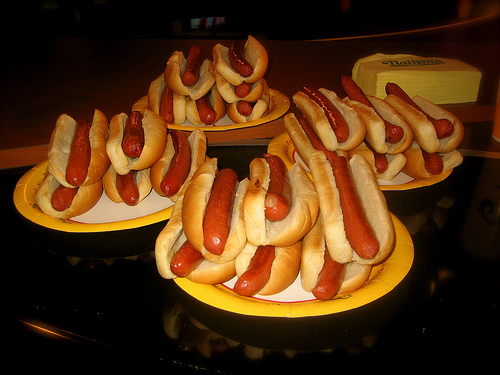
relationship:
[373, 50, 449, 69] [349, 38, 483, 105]
logo on top napkin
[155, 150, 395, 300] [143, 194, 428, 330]
hot dog on plate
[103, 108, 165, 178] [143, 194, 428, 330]
hot dog on plate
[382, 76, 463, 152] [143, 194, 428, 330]
hot dog on plate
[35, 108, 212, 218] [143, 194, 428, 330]
hot dog on plate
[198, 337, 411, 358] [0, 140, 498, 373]
reflection on surface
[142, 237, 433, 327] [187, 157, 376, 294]
plate full of hot dogs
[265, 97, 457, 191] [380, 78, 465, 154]
paper plate full of hot dogs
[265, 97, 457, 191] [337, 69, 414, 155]
paper plate full of hot dogs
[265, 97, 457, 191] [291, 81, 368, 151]
paper plate full of hot dogs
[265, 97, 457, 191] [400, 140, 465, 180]
paper plate full of hot dogs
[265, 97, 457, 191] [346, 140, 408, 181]
paper plate full of hot dogs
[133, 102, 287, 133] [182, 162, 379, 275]
plate full of hot dogs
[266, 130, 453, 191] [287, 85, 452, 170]
paper plate full of hot dogs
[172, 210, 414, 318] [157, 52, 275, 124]
plate full of hot dogs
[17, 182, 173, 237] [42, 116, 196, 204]
plate full of hot dogs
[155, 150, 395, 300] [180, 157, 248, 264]
hot dog in bun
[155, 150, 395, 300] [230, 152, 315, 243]
hot dog in bun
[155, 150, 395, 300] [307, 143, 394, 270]
hot dog in bun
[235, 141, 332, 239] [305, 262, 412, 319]
hot dog on plate